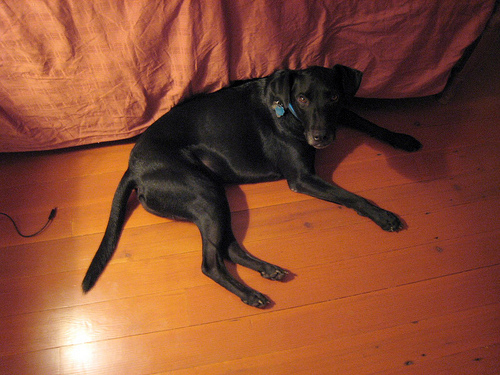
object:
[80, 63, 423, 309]
dog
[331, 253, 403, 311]
floor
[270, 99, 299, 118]
collar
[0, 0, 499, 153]
bed